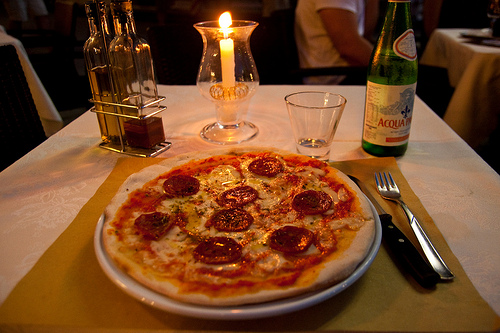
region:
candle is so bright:
[128, 10, 298, 190]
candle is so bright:
[162, 5, 414, 330]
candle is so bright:
[157, 5, 259, 145]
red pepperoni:
[191, 231, 243, 266]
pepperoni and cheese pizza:
[96, 147, 377, 315]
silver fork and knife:
[348, 170, 456, 290]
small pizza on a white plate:
[93, 141, 382, 317]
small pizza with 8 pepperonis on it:
[93, 150, 380, 309]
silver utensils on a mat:
[348, 161, 457, 306]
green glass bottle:
[361, 2, 420, 162]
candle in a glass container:
[189, 6, 264, 146]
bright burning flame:
[216, 6, 235, 38]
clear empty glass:
[279, 80, 346, 159]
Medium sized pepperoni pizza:
[121, 164, 368, 285]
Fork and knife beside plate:
[349, 172, 457, 299]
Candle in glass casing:
[203, 24, 266, 139]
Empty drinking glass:
[286, 82, 345, 149]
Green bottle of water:
[378, 0, 414, 160]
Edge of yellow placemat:
[5, 158, 127, 329]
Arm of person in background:
[322, 7, 372, 69]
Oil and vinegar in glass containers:
[88, 58, 199, 175]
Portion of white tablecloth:
[25, 157, 92, 200]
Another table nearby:
[441, 30, 499, 134]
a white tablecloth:
[0, 81, 497, 329]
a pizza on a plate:
[100, 142, 381, 303]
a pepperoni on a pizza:
[266, 217, 311, 248]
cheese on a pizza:
[122, 155, 362, 280]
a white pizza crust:
[100, 142, 375, 302]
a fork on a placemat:
[370, 165, 450, 281]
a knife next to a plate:
[346, 166, 438, 287]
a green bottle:
[361, 0, 424, 159]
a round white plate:
[90, 181, 380, 312]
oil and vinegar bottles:
[75, 0, 170, 150]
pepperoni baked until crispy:
[292, 185, 338, 216]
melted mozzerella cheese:
[199, 164, 246, 188]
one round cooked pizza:
[101, 150, 376, 307]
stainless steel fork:
[374, 162, 441, 294]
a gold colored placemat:
[2, 143, 498, 331]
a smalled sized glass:
[281, 90, 356, 156]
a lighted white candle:
[218, 7, 236, 141]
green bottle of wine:
[364, 2, 427, 164]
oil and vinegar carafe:
[73, 4, 171, 162]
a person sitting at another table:
[297, 0, 390, 99]